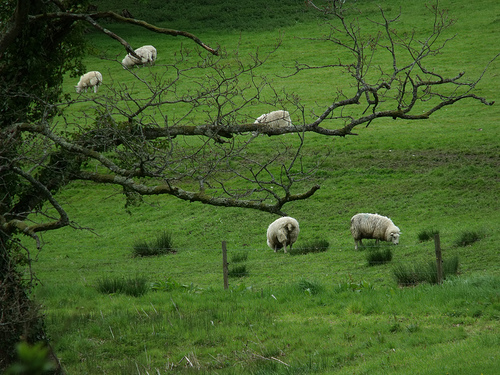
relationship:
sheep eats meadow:
[345, 210, 403, 253] [1, 1, 497, 374]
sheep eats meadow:
[261, 214, 304, 255] [1, 1, 497, 374]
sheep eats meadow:
[116, 43, 160, 72] [1, 1, 497, 374]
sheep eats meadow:
[72, 66, 106, 98] [1, 1, 497, 374]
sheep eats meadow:
[252, 105, 293, 139] [1, 1, 497, 374]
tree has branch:
[0, 3, 95, 374] [2, 5, 230, 67]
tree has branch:
[0, 3, 95, 374] [0, 168, 336, 214]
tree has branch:
[0, 3, 95, 374] [0, 2, 500, 239]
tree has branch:
[0, 3, 95, 374] [6, 164, 109, 259]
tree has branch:
[0, 3, 95, 374] [1, 40, 293, 179]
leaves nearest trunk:
[0, 0, 183, 374] [0, 1, 25, 374]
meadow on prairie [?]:
[1, 1, 497, 374] [1, 0, 499, 374]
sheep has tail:
[261, 214, 304, 255] [284, 219, 295, 233]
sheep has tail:
[345, 210, 403, 253] [348, 216, 358, 226]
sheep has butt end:
[261, 214, 304, 255] [278, 217, 300, 238]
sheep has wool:
[261, 214, 304, 255] [265, 217, 303, 243]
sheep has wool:
[345, 210, 403, 253] [348, 210, 391, 244]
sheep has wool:
[252, 105, 293, 139] [260, 108, 291, 130]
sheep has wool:
[116, 43, 160, 72] [127, 48, 149, 64]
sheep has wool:
[116, 43, 160, 72] [135, 44, 157, 57]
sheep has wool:
[72, 66, 106, 98] [80, 69, 101, 84]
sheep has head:
[345, 210, 403, 253] [387, 226, 404, 247]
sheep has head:
[261, 214, 304, 255] [264, 241, 280, 254]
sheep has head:
[72, 66, 106, 98] [73, 84, 86, 96]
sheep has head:
[116, 43, 160, 72] [120, 58, 131, 74]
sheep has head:
[252, 105, 293, 139] [249, 127, 260, 139]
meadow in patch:
[1, 1, 497, 374] [131, 226, 180, 261]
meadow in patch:
[1, 1, 497, 374] [92, 270, 146, 300]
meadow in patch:
[1, 1, 497, 374] [387, 256, 459, 289]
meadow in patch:
[1, 1, 497, 374] [364, 248, 393, 263]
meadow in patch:
[1, 1, 497, 374] [287, 237, 331, 256]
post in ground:
[219, 237, 232, 291] [14, 0, 500, 372]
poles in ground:
[435, 230, 445, 285] [14, 0, 500, 372]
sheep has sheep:
[116, 43, 160, 72] [116, 43, 160, 72]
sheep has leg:
[261, 214, 304, 255] [281, 242, 288, 255]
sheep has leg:
[345, 210, 403, 253] [350, 234, 359, 252]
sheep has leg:
[72, 66, 106, 98] [92, 84, 98, 95]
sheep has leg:
[116, 43, 160, 72] [141, 61, 147, 69]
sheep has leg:
[345, 210, 403, 253] [359, 235, 365, 248]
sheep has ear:
[345, 210, 403, 253] [387, 230, 397, 238]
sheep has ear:
[345, 210, 403, 253] [396, 228, 404, 236]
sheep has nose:
[345, 210, 403, 253] [393, 241, 400, 248]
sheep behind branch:
[252, 105, 293, 139] [0, 2, 500, 239]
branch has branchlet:
[0, 2, 500, 239] [315, 13, 463, 126]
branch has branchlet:
[0, 2, 500, 239] [311, 0, 496, 143]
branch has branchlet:
[0, 168, 336, 214] [230, 157, 294, 196]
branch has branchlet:
[0, 168, 336, 214] [145, 163, 178, 193]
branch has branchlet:
[6, 164, 109, 259] [60, 218, 105, 243]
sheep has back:
[345, 210, 403, 253] [350, 210, 392, 228]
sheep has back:
[261, 214, 304, 255] [254, 215, 297, 226]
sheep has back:
[252, 105, 293, 139] [251, 105, 292, 118]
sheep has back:
[116, 43, 160, 72] [117, 48, 151, 54]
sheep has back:
[72, 66, 106, 98] [72, 70, 102, 78]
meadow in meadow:
[1, 1, 497, 374] [1, 1, 497, 374]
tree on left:
[0, 3, 95, 374] [2, 1, 248, 373]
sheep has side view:
[345, 210, 403, 253] [348, 210, 404, 253]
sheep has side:
[252, 105, 293, 139] [265, 222, 287, 247]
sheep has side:
[252, 105, 293, 139] [257, 113, 285, 129]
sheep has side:
[116, 43, 160, 72] [122, 49, 147, 66]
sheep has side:
[72, 66, 106, 98] [77, 71, 97, 87]